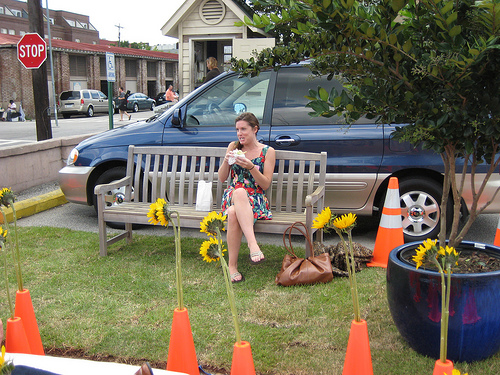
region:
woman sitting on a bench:
[218, 107, 277, 290]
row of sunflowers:
[0, 183, 461, 362]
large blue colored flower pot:
[381, 235, 498, 358]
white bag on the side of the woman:
[192, 176, 214, 218]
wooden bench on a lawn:
[89, 137, 329, 272]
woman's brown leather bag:
[273, 215, 336, 294]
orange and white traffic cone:
[361, 168, 408, 277]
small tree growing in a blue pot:
[305, 109, 499, 261]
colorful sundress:
[218, 141, 272, 221]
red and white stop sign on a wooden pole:
[16, 25, 51, 74]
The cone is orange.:
[153, 292, 213, 373]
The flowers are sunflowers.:
[143, 192, 208, 357]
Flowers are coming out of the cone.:
[146, 183, 208, 337]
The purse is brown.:
[266, 219, 328, 284]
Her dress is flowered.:
[189, 119, 287, 247]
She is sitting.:
[195, 103, 283, 283]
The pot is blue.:
[373, 231, 488, 328]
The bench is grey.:
[56, 138, 394, 270]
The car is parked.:
[26, 65, 483, 233]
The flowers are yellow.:
[297, 221, 354, 241]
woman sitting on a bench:
[177, 86, 289, 325]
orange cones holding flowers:
[128, 198, 395, 367]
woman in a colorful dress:
[204, 111, 288, 265]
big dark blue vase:
[372, 221, 498, 354]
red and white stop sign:
[11, 28, 80, 153]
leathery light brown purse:
[265, 212, 340, 296]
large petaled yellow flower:
[145, 199, 183, 243]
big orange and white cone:
[370, 164, 415, 292]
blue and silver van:
[78, 30, 479, 240]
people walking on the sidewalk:
[91, 57, 226, 137]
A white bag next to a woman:
[196, 111, 273, 288]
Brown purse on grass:
[264, 222, 342, 332]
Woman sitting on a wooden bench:
[87, 111, 328, 297]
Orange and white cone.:
[366, 175, 408, 277]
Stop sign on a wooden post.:
[14, 0, 70, 138]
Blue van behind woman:
[53, 46, 498, 260]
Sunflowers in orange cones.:
[136, 194, 474, 373]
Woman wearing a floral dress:
[211, 108, 283, 285]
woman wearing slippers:
[223, 112, 275, 288]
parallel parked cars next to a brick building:
[2, 42, 157, 119]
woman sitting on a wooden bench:
[58, 124, 378, 269]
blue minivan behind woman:
[63, 60, 474, 274]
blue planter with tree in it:
[330, 36, 499, 363]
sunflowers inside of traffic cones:
[115, 195, 370, 373]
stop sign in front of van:
[15, 30, 68, 128]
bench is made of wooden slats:
[97, 143, 332, 257]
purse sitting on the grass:
[273, 213, 344, 305]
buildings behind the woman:
[5, 28, 192, 120]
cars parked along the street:
[12, 32, 175, 117]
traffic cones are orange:
[158, 298, 207, 373]